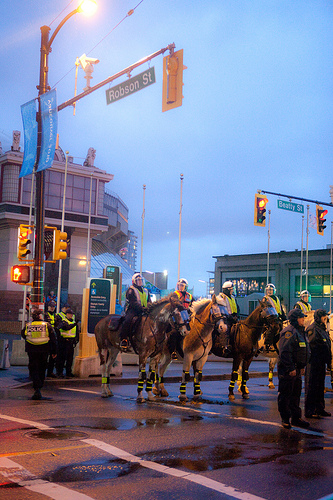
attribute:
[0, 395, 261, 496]
line — white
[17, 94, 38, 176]
banner — blue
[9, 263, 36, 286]
pedestrian sign — lit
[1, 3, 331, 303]
sky — blue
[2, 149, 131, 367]
building — tall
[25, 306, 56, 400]
cop — standing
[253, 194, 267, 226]
trafficlight — above, lit, red